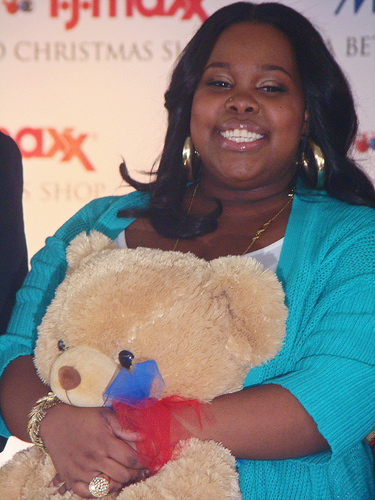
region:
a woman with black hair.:
[105, 2, 373, 249]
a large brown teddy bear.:
[0, 224, 289, 498]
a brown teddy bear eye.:
[111, 334, 154, 371]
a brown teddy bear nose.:
[53, 355, 93, 398]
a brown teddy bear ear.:
[205, 246, 289, 369]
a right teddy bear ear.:
[59, 217, 119, 279]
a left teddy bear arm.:
[96, 395, 249, 497]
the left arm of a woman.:
[84, 370, 336, 498]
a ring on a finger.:
[80, 473, 115, 498]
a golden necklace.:
[133, 203, 293, 263]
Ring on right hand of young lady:
[84, 470, 109, 496]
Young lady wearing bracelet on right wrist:
[7, 382, 69, 454]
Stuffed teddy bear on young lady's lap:
[3, 228, 291, 495]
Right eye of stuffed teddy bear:
[44, 328, 71, 359]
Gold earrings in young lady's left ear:
[296, 135, 326, 180]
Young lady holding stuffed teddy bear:
[3, 3, 368, 493]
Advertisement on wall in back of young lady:
[3, 3, 371, 176]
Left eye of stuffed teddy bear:
[107, 345, 145, 375]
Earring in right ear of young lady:
[166, 124, 199, 172]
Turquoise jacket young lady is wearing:
[0, 173, 372, 497]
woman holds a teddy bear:
[0, 4, 373, 499]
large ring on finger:
[81, 474, 119, 498]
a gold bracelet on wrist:
[21, 389, 81, 459]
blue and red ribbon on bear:
[103, 365, 219, 478]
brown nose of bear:
[56, 365, 86, 394]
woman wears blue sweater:
[4, 198, 374, 487]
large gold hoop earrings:
[177, 133, 203, 188]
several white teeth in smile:
[218, 126, 269, 146]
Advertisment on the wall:
[11, 1, 212, 79]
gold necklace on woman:
[160, 177, 290, 279]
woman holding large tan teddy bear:
[1, 0, 373, 498]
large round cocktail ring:
[86, 476, 109, 499]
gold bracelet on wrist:
[26, 391, 62, 449]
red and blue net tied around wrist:
[102, 359, 212, 477]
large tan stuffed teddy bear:
[0, 230, 288, 498]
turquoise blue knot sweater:
[0, 174, 374, 498]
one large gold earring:
[296, 134, 331, 189]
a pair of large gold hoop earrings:
[179, 134, 327, 190]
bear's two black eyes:
[56, 338, 134, 370]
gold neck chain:
[174, 179, 294, 258]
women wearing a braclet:
[25, 402, 65, 440]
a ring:
[88, 476, 106, 497]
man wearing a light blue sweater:
[308, 237, 372, 391]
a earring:
[300, 144, 338, 194]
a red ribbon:
[123, 406, 182, 462]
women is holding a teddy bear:
[47, 256, 225, 472]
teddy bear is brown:
[85, 266, 236, 373]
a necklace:
[243, 212, 281, 238]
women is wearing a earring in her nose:
[226, 96, 235, 102]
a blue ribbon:
[109, 374, 157, 405]